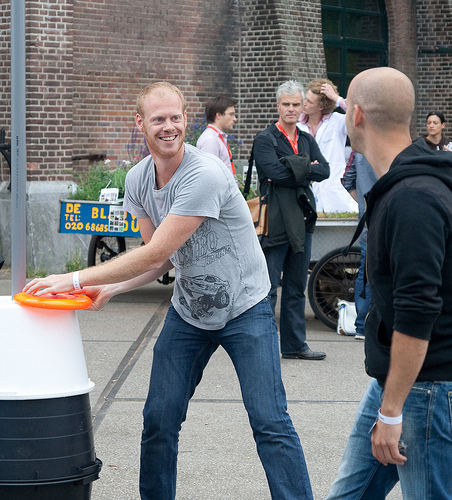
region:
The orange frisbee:
[12, 281, 92, 313]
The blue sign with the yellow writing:
[52, 195, 143, 239]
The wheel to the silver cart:
[303, 240, 364, 332]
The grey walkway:
[2, 270, 402, 497]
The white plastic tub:
[0, 289, 96, 405]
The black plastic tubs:
[0, 392, 105, 498]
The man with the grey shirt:
[20, 77, 317, 498]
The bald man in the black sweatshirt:
[314, 61, 451, 498]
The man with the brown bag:
[239, 75, 328, 363]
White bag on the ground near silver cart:
[334, 294, 357, 338]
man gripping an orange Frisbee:
[18, 74, 232, 327]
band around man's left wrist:
[55, 260, 89, 293]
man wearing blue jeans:
[135, 295, 312, 496]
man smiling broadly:
[131, 85, 183, 151]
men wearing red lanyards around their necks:
[194, 88, 311, 181]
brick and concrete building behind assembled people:
[2, 1, 443, 271]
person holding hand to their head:
[301, 71, 345, 133]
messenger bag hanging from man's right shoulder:
[232, 79, 300, 237]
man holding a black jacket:
[246, 76, 335, 255]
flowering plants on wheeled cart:
[65, 98, 249, 289]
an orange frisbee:
[8, 279, 100, 315]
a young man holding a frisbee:
[10, 81, 338, 494]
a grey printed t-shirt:
[115, 149, 273, 332]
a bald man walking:
[301, 65, 448, 495]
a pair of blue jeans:
[133, 298, 313, 496]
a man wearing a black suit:
[243, 78, 328, 367]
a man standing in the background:
[197, 96, 241, 172]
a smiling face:
[125, 81, 191, 161]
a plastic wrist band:
[370, 401, 409, 431]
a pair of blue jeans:
[324, 365, 446, 498]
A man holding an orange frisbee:
[20, 75, 264, 360]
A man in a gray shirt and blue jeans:
[102, 72, 282, 493]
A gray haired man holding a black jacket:
[245, 76, 330, 280]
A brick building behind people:
[27, 0, 446, 202]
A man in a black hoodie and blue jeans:
[337, 64, 451, 498]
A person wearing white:
[300, 83, 358, 209]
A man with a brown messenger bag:
[242, 81, 332, 253]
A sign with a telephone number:
[61, 202, 134, 238]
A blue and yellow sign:
[63, 198, 133, 238]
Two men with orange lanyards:
[202, 75, 320, 206]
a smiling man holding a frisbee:
[17, 81, 312, 498]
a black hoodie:
[352, 139, 448, 389]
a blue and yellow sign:
[56, 197, 138, 236]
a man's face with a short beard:
[132, 78, 192, 162]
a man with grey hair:
[270, 77, 304, 126]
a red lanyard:
[203, 121, 235, 173]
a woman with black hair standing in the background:
[412, 108, 449, 151]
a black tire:
[305, 242, 363, 334]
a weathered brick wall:
[30, 3, 320, 77]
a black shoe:
[278, 342, 329, 363]